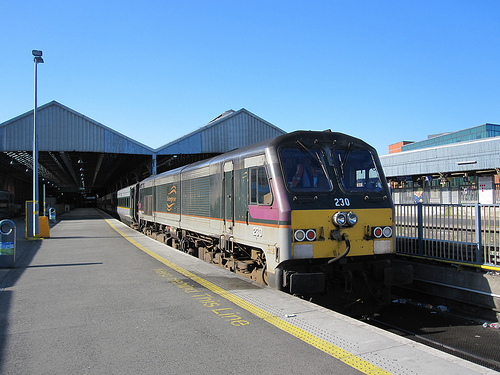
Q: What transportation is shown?
A: A train.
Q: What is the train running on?
A: Train tracks.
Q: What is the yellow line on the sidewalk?
A: Caution stripe.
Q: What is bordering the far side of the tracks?
A: Metal fence.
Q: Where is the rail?
A: By track.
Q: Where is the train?
A: Station.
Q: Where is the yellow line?
A: On ground.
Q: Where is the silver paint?
A: Roof.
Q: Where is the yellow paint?
A: On front.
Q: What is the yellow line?
A: Caution line.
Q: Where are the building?
A: Behind train.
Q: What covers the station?
A: Metal.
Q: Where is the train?
A: On track.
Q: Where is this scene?
A: At the train station.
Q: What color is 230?
A: White.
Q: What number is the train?
A: 230.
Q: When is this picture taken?
A: During the day time.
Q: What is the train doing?
A: Leaving the station.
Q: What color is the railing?
A: Blue.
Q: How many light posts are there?
A: 1.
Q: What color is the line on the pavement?
A: Yellow.